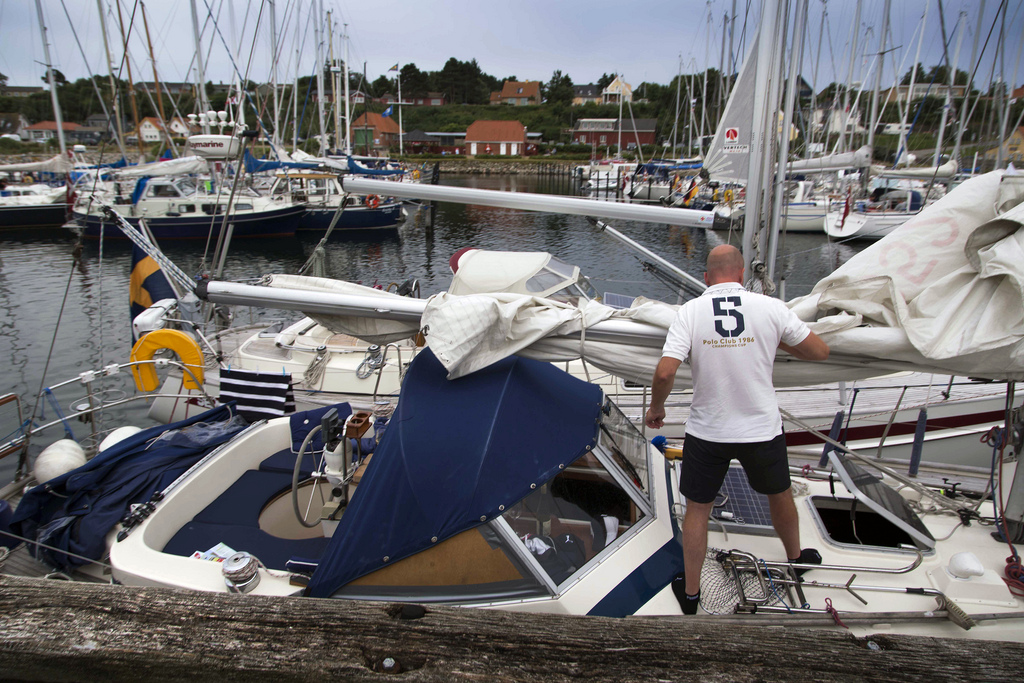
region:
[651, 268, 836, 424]
man wear a white shirt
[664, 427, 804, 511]
man wearing black shorts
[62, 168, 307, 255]
blue and white boat in dock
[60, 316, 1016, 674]
blue and white boat in dock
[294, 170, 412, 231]
blue and white boat in dock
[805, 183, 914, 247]
white boat in the dock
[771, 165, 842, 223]
white boat in the dock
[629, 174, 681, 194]
white boat in the dock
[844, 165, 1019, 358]
white sail on the boat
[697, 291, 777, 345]
number 5 on the shirt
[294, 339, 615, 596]
the cover over the windshield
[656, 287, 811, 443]
the white polo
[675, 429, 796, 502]
a pair of black shorts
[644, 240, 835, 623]
a man standing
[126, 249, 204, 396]
the gold floaters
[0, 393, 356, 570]
the navy interior of the boat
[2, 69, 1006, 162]
the buildings on shore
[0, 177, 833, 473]
the still waters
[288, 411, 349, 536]
the stirring wheel on the boat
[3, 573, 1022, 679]
the wall on the side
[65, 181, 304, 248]
blue and white boat sitting in body of water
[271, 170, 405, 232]
blue and white boat sitting in body of water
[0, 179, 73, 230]
blue and white boat sitting in body of water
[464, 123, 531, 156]
small brick building with white windows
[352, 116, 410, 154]
small brick building with large green door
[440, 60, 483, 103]
full, green trees sitting on hill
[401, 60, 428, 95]
full, green trees sitting on hill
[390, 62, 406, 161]
tall flag waving in the wind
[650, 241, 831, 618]
man standing on a blue and white boat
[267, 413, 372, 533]
steering wheel on the boat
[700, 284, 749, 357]
blue 5 on the back of the man's shirt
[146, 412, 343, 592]
blue cushions on the seats of the boat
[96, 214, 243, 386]
blue and yellow flag